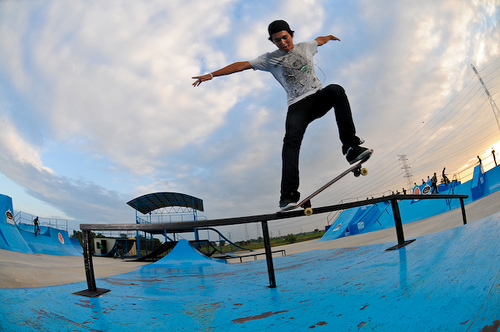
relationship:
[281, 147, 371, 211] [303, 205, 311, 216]
skateboard has wheels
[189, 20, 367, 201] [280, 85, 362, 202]
boy has jeans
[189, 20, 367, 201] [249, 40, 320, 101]
boy has white shirt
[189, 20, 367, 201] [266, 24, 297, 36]
boy has dark hair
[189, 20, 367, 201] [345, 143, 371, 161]
boy has sneakers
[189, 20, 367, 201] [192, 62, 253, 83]
boy has arms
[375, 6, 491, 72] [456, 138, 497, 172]
clouds in front of sun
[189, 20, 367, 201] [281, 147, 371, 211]
boy on skateboard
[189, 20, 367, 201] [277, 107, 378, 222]
boy doing tricks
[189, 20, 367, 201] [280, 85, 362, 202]
boy wearing pants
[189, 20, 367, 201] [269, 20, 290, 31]
boy wearing hat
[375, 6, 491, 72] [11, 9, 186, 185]
clouds in sky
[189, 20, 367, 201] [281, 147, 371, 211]
boy on a skateboard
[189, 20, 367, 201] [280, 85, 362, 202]
skateboarder wearing pants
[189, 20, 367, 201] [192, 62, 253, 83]
man has arms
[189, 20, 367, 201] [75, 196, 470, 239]
man on railing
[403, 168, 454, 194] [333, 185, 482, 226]
people are on ramp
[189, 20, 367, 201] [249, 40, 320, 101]
man has a shirt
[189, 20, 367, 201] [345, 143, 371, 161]
man has on sneakers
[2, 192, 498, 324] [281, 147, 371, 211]
area has skateboards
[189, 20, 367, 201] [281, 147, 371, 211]
man on a skateboard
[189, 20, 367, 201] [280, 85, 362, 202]
man wearing pants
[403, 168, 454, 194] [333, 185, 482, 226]
people are on a ramp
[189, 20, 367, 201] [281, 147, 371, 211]
man using skateboard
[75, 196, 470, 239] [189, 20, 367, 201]
rail has a skateboarder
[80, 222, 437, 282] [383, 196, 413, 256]
rail has a leg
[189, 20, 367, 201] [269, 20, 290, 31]
man has a hat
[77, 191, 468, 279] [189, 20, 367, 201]
rail has a skateboarder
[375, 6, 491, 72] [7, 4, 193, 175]
clouds are in background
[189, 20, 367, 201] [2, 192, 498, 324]
skateboarder in skatepark